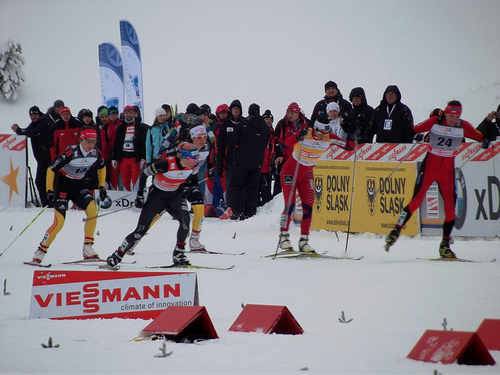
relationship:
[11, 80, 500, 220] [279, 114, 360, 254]
spectators behind person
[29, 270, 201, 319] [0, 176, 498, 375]
sign on snow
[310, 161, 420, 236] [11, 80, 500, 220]
sign in front of spectators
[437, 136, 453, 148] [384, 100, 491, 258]
number 24 on person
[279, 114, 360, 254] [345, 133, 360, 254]
person holding ski pole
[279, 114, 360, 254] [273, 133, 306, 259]
person holding ski pole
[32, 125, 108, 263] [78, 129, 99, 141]
person wearing headband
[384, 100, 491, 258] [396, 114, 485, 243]
person wearing ski suit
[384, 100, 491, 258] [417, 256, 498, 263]
person on skis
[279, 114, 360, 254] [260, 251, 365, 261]
person on skis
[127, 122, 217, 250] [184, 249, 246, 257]
person on skis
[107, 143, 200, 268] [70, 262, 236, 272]
person on skis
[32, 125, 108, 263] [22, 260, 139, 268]
person on skis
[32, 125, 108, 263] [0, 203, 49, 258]
person holding ski pole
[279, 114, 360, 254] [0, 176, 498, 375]
person on snow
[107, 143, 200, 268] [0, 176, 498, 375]
person on snow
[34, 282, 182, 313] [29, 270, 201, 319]
lettering on sign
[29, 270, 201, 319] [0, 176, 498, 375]
sign in snow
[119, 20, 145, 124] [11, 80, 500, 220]
banner behind spectators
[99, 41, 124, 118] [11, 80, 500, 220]
banner behind spectators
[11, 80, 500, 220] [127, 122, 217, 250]
spectators behind person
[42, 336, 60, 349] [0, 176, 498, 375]
plant growing out of snow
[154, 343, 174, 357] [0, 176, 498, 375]
plant growing out of snow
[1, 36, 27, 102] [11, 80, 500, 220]
tree behind spectators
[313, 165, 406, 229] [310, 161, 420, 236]
lettering on sign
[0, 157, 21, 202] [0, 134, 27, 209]
star on sign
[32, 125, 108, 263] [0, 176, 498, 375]
person in snow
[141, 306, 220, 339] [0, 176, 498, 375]
sign in snow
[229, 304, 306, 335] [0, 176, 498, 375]
sign in snow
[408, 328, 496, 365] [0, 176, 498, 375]
sign in snow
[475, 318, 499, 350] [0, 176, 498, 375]
sign in snow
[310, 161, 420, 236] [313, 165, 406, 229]
sign with lettering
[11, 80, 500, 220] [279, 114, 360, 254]
spectators watching person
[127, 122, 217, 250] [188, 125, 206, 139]
person has headband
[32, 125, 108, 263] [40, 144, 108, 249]
person wearing ski suit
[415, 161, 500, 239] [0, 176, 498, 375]
sign in snow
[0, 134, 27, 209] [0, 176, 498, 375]
sign in snow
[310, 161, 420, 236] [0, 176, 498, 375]
sign in snow